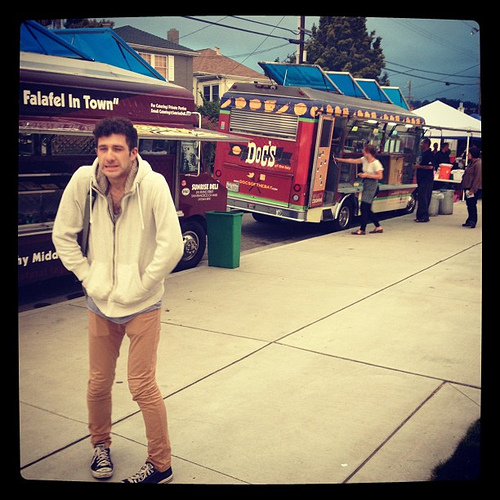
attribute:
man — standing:
[47, 115, 188, 483]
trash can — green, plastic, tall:
[207, 207, 242, 272]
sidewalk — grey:
[19, 191, 490, 480]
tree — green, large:
[296, 12, 394, 85]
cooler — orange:
[434, 158, 453, 181]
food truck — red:
[208, 61, 435, 236]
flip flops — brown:
[349, 225, 387, 237]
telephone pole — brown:
[296, 13, 308, 62]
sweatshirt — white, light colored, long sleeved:
[51, 154, 186, 315]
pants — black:
[463, 186, 481, 227]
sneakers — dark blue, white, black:
[84, 443, 180, 484]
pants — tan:
[79, 307, 181, 475]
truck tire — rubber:
[171, 220, 207, 269]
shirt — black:
[415, 148, 438, 186]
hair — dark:
[90, 118, 142, 149]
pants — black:
[412, 176, 438, 223]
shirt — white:
[359, 156, 384, 177]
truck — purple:
[19, 44, 232, 297]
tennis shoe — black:
[85, 446, 118, 480]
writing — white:
[22, 86, 126, 116]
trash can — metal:
[424, 188, 443, 220]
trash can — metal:
[439, 187, 455, 216]